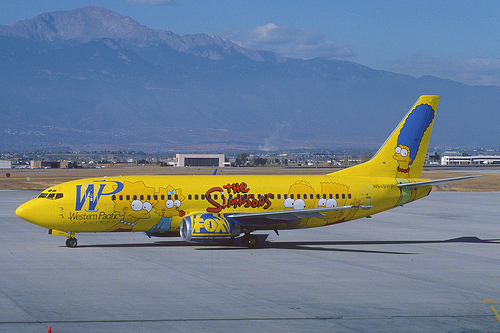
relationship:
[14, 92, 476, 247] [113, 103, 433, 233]
airplane has simpsons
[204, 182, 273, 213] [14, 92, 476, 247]
lettering on airplane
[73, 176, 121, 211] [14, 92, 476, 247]
lettering on airplane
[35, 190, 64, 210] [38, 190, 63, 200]
cockpit has windows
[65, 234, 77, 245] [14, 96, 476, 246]
wheel on airplane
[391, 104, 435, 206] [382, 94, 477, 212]
marge simpson on tail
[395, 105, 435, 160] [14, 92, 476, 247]
paint on airplane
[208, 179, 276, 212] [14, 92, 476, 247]
lettering on airplane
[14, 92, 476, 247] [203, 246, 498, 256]
airplane has shadow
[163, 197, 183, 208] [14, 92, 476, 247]
eyes on airplane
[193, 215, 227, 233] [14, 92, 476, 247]
fox on airplane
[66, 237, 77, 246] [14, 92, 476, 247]
wheel on airplane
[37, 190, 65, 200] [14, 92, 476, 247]
windows on front of airplane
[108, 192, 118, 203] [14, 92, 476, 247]
window on airplane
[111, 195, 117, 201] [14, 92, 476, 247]
window on airplane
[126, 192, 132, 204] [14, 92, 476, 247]
window on airplane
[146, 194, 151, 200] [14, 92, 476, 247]
window on airplane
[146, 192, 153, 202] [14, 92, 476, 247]
window on airplane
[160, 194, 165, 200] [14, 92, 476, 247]
window on airplane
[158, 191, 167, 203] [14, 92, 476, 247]
window on airplane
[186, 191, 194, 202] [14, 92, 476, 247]
window on airplane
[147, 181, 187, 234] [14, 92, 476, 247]
maggie simpson on airplane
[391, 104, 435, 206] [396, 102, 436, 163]
marge simpson has hair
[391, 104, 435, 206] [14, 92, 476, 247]
marge simpson on back of airplane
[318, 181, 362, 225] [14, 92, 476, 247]
bart simpson on airplane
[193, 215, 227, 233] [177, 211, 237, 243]
fox on engine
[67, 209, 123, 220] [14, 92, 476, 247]
western pacific on airplane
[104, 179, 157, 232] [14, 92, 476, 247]
lisa simpson on airplane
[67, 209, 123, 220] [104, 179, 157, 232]
western pacific next to lisa simpson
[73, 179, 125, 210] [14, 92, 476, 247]
lettering on airplane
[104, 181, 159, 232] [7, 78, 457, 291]
lisa simpson on plane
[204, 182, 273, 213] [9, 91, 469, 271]
lettering on plane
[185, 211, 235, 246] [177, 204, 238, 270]
fox on engine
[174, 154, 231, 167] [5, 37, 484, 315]
building in background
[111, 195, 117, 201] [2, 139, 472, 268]
window on airplane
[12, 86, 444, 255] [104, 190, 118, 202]
airplane has window